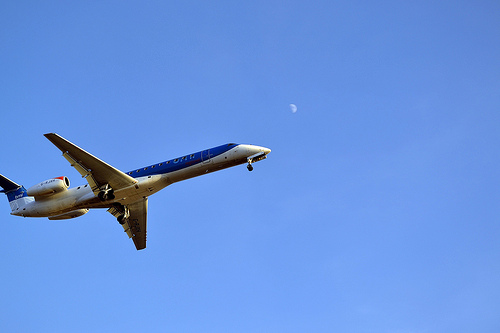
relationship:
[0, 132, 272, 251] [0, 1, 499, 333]
airplane in sky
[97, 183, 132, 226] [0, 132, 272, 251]
landing gear on airplane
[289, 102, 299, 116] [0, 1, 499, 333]
moon in sky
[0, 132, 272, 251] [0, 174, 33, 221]
airplane has tail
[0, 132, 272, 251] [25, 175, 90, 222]
airplane has jets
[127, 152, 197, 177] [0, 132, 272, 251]
windows on airplane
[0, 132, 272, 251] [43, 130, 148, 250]
airplane has wings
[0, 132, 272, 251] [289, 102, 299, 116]
airplane in front of moon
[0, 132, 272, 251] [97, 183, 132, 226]
airplane with landing gear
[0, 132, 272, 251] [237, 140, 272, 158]
airplane with nose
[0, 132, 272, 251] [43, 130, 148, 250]
airplane with wings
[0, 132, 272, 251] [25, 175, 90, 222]
airplane with jets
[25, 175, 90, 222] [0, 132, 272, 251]
jets on airplane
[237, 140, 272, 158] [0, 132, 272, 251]
nose of airplane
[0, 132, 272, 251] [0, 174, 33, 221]
airplane with tail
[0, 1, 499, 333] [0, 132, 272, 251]
sky above airplane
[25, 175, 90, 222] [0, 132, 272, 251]
jets in airplane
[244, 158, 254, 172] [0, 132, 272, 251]
landing gear mounted on airplane